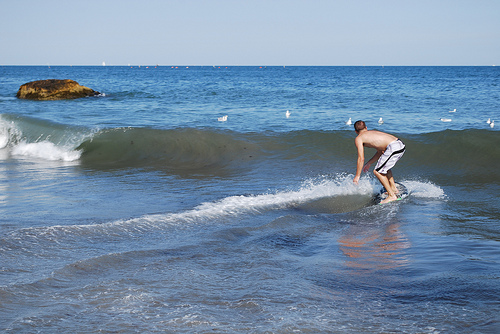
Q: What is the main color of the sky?
A: Blue.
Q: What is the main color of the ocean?
A: Blue.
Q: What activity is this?
A: Surfing.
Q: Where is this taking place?
A: Ocean.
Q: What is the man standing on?
A: Surfboard.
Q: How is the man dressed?
A: In a swimsuit.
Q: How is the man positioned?
A: Partially crouched.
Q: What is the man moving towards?
A: A small wave.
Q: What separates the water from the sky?
A: Horizon.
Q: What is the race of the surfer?
A: Caucasian.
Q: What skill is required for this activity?
A: Balance.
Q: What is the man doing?
A: Surfing.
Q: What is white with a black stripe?
A: Swim trunks.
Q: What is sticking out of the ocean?
A: Rock.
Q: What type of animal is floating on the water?
A: Seagulls.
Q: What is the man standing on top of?
A: Surfboard.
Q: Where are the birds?
A: In the water.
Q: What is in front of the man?
A: Wave.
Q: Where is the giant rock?
A: In the ocean.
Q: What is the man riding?
A: A surfboard.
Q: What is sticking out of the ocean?
A: A rock.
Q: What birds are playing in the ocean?
A: Seagulls.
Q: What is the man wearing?
A: Black and white swimtrunks.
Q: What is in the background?
A: The sky.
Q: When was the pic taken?
A: During the day.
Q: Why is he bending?
A: For balance.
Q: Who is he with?
A: No one.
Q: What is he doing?
A: Surfing.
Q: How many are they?
A: 1.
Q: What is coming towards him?
A: Wave.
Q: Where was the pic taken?
A: The water.